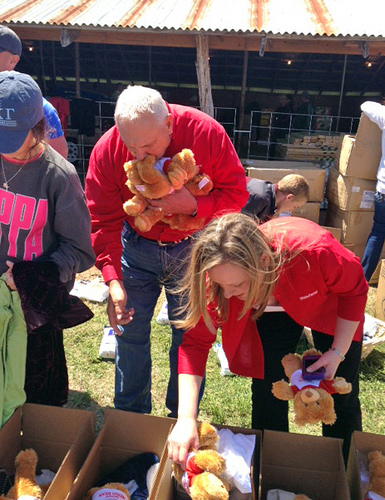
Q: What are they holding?
A: Teddy bears.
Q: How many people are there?
A: 6.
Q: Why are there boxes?
A: For the bears.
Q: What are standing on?
A: Grass.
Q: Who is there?
A: Several people.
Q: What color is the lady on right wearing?
A: Red.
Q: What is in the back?
A: Building.